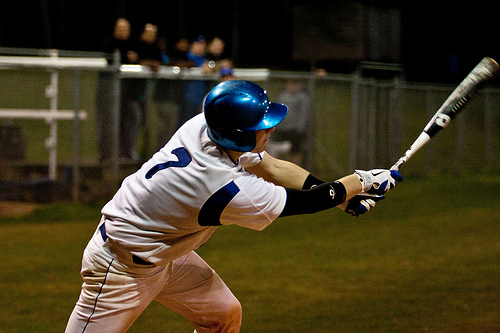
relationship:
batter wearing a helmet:
[65, 55, 499, 333] [199, 74, 288, 154]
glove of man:
[350, 164, 397, 196] [68, 81, 402, 331]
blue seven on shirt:
[146, 146, 191, 180] [63, 76, 399, 331]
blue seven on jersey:
[146, 146, 191, 180] [95, 108, 290, 262]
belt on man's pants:
[80, 224, 191, 263] [63, 228, 242, 333]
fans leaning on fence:
[108, 8, 239, 82] [0, 52, 483, 218]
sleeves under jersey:
[278, 175, 345, 216] [140, 126, 254, 233]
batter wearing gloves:
[118, 73, 349, 278] [349, 159, 406, 207]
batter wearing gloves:
[65, 55, 499, 333] [339, 162, 410, 222]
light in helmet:
[236, 80, 281, 136] [191, 70, 292, 152]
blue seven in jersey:
[146, 146, 191, 180] [98, 114, 292, 271]